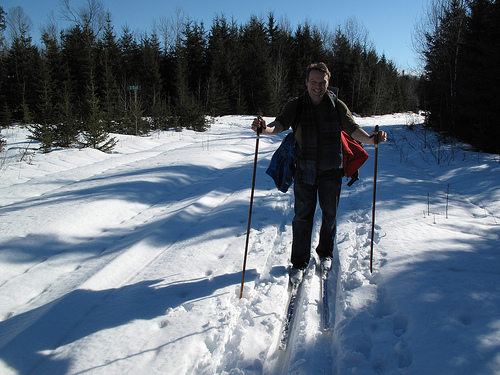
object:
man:
[250, 61, 388, 285]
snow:
[1, 111, 499, 375]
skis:
[277, 284, 302, 353]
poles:
[369, 125, 380, 274]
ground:
[1, 107, 499, 373]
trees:
[2, 0, 499, 158]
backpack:
[341, 129, 364, 187]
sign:
[127, 85, 139, 91]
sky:
[3, 1, 500, 77]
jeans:
[290, 164, 343, 265]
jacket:
[275, 89, 360, 172]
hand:
[371, 130, 388, 145]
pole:
[370, 125, 379, 274]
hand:
[251, 116, 267, 134]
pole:
[239, 115, 261, 299]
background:
[3, 1, 500, 167]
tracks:
[277, 272, 306, 353]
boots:
[289, 255, 306, 285]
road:
[4, 56, 430, 375]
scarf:
[301, 89, 337, 186]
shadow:
[0, 268, 264, 373]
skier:
[251, 61, 387, 284]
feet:
[319, 252, 333, 271]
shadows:
[265, 229, 500, 371]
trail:
[8, 113, 420, 375]